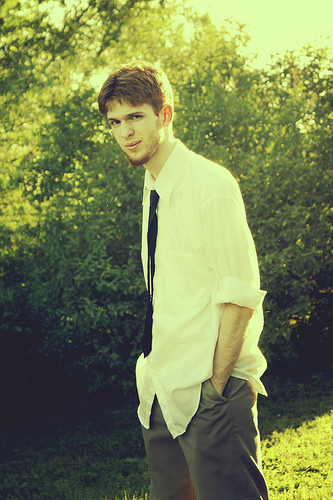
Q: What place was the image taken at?
A: It was taken at the garden.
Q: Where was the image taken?
A: It was taken at the garden.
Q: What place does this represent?
A: It represents the garden.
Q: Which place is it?
A: It is a garden.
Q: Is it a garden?
A: Yes, it is a garden.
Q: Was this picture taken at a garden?
A: Yes, it was taken in a garden.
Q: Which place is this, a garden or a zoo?
A: It is a garden.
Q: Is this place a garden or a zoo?
A: It is a garden.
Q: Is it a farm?
A: No, it is a garden.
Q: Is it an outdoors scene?
A: Yes, it is outdoors.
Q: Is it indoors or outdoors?
A: It is outdoors.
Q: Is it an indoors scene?
A: No, it is outdoors.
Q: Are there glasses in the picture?
A: No, there are no glasses.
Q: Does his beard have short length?
A: Yes, the beard is short.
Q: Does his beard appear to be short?
A: Yes, the beard is short.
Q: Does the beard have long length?
A: No, the beard is short.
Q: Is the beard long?
A: No, the beard is short.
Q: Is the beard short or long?
A: The beard is short.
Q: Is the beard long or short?
A: The beard is short.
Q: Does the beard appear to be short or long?
A: The beard is short.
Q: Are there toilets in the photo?
A: No, there are no toilets.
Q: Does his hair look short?
A: Yes, the hair is short.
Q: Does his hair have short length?
A: Yes, the hair is short.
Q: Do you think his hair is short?
A: Yes, the hair is short.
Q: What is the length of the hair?
A: The hair is short.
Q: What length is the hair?
A: The hair is short.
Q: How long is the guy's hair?
A: The hair is short.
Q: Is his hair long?
A: No, the hair is short.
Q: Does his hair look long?
A: No, the hair is short.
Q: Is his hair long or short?
A: The hair is short.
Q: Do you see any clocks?
A: No, there are no clocks.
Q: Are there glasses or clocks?
A: No, there are no clocks or glasses.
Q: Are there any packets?
A: No, there are no packets.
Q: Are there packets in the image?
A: No, there are no packets.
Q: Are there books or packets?
A: No, there are no packets or books.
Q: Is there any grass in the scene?
A: Yes, there is grass.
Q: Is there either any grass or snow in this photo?
A: Yes, there is grass.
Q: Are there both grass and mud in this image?
A: No, there is grass but no mud.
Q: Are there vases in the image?
A: No, there are no vases.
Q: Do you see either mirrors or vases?
A: No, there are no vases or mirrors.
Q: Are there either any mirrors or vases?
A: No, there are no vases or mirrors.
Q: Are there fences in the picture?
A: No, there are no fences.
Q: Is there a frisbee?
A: No, there are no frisbees.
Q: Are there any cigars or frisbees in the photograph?
A: No, there are no frisbees or cigars.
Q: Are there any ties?
A: Yes, there is a tie.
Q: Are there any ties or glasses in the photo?
A: Yes, there is a tie.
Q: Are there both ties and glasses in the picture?
A: No, there is a tie but no glasses.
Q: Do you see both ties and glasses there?
A: No, there is a tie but no glasses.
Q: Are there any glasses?
A: No, there are no glasses.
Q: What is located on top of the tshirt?
A: The necktie is on top of the tshirt.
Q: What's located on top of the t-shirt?
A: The necktie is on top of the tshirt.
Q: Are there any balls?
A: No, there are no balls.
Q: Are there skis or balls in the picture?
A: No, there are no balls or skis.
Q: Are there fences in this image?
A: No, there are no fences.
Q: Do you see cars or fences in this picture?
A: No, there are no fences or cars.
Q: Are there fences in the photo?
A: No, there are no fences.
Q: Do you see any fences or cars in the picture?
A: No, there are no fences or cars.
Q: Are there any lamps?
A: No, there are no lamps.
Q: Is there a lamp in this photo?
A: No, there are no lamps.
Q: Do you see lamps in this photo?
A: No, there are no lamps.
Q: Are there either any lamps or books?
A: No, there are no lamps or books.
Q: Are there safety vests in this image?
A: No, there are no safety vests.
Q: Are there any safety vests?
A: No, there are no safety vests.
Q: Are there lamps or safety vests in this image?
A: No, there are no safety vests or lamps.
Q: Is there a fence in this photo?
A: No, there are no fences.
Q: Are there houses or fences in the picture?
A: No, there are no fences or houses.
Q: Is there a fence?
A: No, there are no fences.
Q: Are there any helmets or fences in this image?
A: No, there are no fences or helmets.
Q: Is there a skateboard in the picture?
A: No, there are no skateboards.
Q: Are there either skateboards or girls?
A: No, there are no skateboards or girls.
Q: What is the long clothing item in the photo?
A: The clothing item is a t-shirt.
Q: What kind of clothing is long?
A: The clothing is a t-shirt.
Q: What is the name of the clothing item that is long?
A: The clothing item is a t-shirt.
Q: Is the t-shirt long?
A: Yes, the t-shirt is long.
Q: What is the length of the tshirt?
A: The tshirt is long.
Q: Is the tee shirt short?
A: No, the tee shirt is long.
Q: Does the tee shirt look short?
A: No, the tee shirt is long.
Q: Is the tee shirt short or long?
A: The tee shirt is long.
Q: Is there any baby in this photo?
A: No, there are no babies.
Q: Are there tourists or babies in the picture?
A: No, there are no babies or tourists.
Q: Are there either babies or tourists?
A: No, there are no babies or tourists.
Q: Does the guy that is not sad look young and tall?
A: Yes, the guy is young and tall.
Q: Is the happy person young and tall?
A: Yes, the guy is young and tall.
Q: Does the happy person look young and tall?
A: Yes, the guy is young and tall.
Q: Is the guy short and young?
A: No, the guy is young but tall.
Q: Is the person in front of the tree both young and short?
A: No, the guy is young but tall.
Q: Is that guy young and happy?
A: Yes, the guy is young and happy.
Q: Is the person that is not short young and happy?
A: Yes, the guy is young and happy.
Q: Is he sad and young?
A: No, the guy is young but happy.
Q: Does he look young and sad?
A: No, the guy is young but happy.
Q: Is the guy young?
A: Yes, the guy is young.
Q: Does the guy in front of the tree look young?
A: Yes, the guy is young.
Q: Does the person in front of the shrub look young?
A: Yes, the guy is young.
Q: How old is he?
A: The guy is young.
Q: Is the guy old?
A: No, the guy is young.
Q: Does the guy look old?
A: No, the guy is young.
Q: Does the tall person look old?
A: No, the guy is young.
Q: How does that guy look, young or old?
A: The guy is young.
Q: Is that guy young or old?
A: The guy is young.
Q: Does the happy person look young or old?
A: The guy is young.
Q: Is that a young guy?
A: Yes, that is a young guy.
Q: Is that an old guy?
A: No, that is a young guy.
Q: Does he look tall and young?
A: Yes, the guy is tall and young.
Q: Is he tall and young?
A: Yes, the guy is tall and young.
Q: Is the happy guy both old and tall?
A: No, the guy is tall but young.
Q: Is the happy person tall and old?
A: No, the guy is tall but young.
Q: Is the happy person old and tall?
A: No, the guy is tall but young.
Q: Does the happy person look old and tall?
A: No, the guy is tall but young.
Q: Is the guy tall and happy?
A: Yes, the guy is tall and happy.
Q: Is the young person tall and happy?
A: Yes, the guy is tall and happy.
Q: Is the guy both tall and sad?
A: No, the guy is tall but happy.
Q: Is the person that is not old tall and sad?
A: No, the guy is tall but happy.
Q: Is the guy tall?
A: Yes, the guy is tall.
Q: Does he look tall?
A: Yes, the guy is tall.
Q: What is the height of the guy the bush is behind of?
A: The guy is tall.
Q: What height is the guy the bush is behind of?
A: The guy is tall.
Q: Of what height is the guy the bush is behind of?
A: The guy is tall.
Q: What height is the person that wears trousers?
A: The guy is tall.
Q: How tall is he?
A: The guy is tall.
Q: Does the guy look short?
A: No, the guy is tall.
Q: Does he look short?
A: No, the guy is tall.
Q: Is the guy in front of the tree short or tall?
A: The guy is tall.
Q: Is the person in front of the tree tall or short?
A: The guy is tall.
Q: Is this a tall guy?
A: Yes, this is a tall guy.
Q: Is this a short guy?
A: No, this is a tall guy.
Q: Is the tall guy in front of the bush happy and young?
A: Yes, the guy is happy and young.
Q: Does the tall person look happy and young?
A: Yes, the guy is happy and young.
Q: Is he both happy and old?
A: No, the guy is happy but young.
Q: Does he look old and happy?
A: No, the guy is happy but young.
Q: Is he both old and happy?
A: No, the guy is happy but young.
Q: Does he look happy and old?
A: No, the guy is happy but young.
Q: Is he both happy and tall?
A: Yes, the guy is happy and tall.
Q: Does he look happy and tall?
A: Yes, the guy is happy and tall.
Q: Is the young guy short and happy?
A: No, the guy is happy but tall.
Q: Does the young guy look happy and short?
A: No, the guy is happy but tall.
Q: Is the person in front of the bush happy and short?
A: No, the guy is happy but tall.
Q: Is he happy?
A: Yes, the guy is happy.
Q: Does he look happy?
A: Yes, the guy is happy.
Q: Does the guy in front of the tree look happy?
A: Yes, the guy is happy.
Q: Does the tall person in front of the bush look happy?
A: Yes, the guy is happy.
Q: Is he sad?
A: No, the guy is happy.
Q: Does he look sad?
A: No, the guy is happy.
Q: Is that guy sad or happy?
A: The guy is happy.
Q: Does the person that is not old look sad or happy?
A: The guy is happy.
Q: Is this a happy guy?
A: Yes, this is a happy guy.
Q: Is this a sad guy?
A: No, this is a happy guy.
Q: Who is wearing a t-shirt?
A: The guy is wearing a t-shirt.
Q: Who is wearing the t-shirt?
A: The guy is wearing a t-shirt.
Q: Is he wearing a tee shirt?
A: Yes, the guy is wearing a tee shirt.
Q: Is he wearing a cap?
A: No, the guy is wearing a tee shirt.